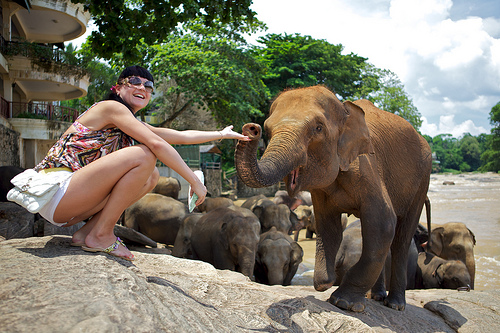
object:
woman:
[18, 66, 251, 262]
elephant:
[235, 85, 433, 313]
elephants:
[190, 203, 262, 281]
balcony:
[0, 38, 92, 101]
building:
[0, 0, 89, 200]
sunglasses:
[120, 76, 153, 94]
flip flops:
[74, 235, 136, 259]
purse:
[4, 168, 66, 215]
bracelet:
[217, 131, 224, 144]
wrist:
[210, 128, 227, 142]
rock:
[0, 233, 497, 330]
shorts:
[30, 170, 71, 228]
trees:
[121, 35, 266, 176]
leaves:
[155, 58, 168, 68]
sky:
[78, 0, 498, 133]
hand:
[218, 124, 250, 144]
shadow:
[234, 295, 466, 332]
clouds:
[166, 0, 498, 144]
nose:
[230, 122, 307, 187]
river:
[414, 170, 497, 291]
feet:
[83, 232, 132, 260]